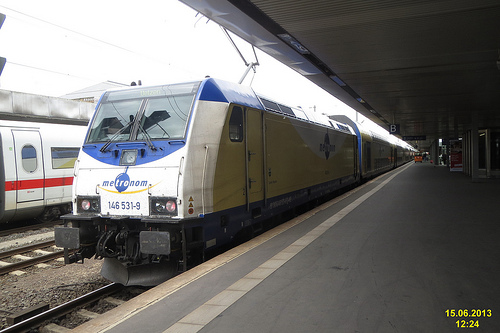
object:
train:
[54, 75, 416, 286]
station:
[0, 0, 499, 332]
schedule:
[139, 89, 162, 96]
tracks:
[0, 248, 73, 275]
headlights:
[165, 199, 178, 213]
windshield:
[87, 94, 195, 142]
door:
[244, 108, 266, 194]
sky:
[13, 1, 159, 64]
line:
[163, 162, 415, 332]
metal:
[213, 5, 236, 22]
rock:
[36, 273, 53, 279]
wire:
[0, 4, 137, 54]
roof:
[210, 77, 356, 136]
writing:
[102, 179, 147, 187]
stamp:
[444, 307, 492, 327]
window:
[227, 105, 245, 143]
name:
[318, 142, 336, 152]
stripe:
[4, 176, 75, 191]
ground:
[395, 222, 443, 249]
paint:
[198, 80, 231, 103]